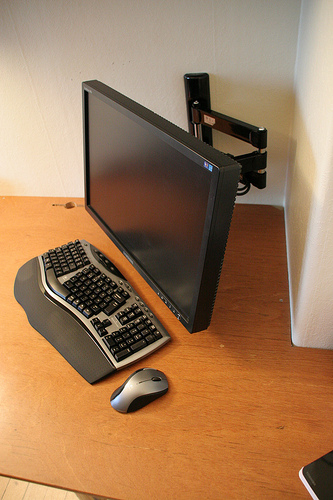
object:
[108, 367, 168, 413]
mouse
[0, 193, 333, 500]
desk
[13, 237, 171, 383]
keyboard